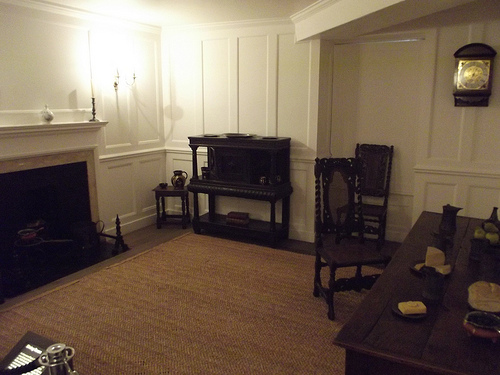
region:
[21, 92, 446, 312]
A dining room with a fireplace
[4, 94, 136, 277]
The fireplace is painted white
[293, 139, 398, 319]
The chair is made of wood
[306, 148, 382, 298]
The chair is an antique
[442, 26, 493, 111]
A clock on the wall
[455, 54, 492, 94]
The face of the clock is fancy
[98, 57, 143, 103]
Lights on the wall are lit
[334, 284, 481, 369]
This table is made of heavy wood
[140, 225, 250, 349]
A large area rug on the floor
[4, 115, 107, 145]
The mantle on the fireplace is white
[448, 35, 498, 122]
clock hanging on a wall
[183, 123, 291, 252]
wooden hutch lining the wall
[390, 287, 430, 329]
dish of butter on a table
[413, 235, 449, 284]
plate of cheese on a table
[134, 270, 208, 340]
natural fiber rug on the floor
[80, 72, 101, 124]
candlestick on a mantle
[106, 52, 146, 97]
wall sconces lit up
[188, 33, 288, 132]
decorative waintscotting on a wall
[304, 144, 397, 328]
two wooden chairs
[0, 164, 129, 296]
darkened fireplace in a living room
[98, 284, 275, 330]
brown carpet on the floor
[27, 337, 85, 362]
silver edge of decanter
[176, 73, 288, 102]
white paint on the wall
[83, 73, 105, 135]
silver candle holder on the mantle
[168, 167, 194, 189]
small silver jug on table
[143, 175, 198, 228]
small brown table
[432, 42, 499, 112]
silver and brown clock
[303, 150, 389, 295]
dark brown oak chair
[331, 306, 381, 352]
edge of brown table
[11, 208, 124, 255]
pokers in the fire place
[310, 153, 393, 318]
the dark wooden high backed chair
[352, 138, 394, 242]
the dark wooden high backed chair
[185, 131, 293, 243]
the dark wooden high large shelf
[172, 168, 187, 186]
a dark metal picture on the table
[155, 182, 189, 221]
a small dark wooden table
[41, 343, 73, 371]
the top of a silver rope pole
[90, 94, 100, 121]
a metal candlelabra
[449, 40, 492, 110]
a dark wooden and gold clock on the wall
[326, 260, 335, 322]
the leg of a dark wooden chair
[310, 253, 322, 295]
the leg of a dark wooden chair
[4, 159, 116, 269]
a black fire place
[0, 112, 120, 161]
a white mantle above fireplace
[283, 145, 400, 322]
two old brown chairs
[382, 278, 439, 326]
a whte square on table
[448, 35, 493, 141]
a clock on the wall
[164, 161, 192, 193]
a water jug in corner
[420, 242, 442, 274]
a wedge of cheese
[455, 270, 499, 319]
a loaf of bread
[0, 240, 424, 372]
a tan rug on the floor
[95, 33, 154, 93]
two wall lamps are on